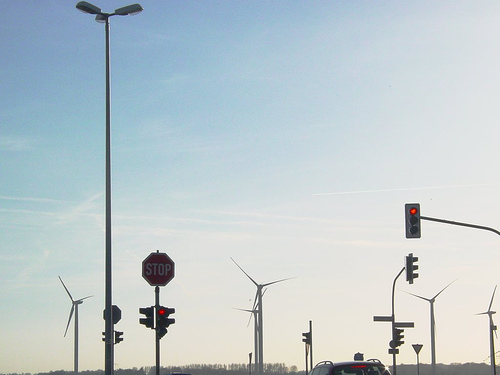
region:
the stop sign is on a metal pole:
[139, 249, 180, 287]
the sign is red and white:
[138, 250, 179, 285]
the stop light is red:
[401, 203, 427, 238]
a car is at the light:
[305, 356, 394, 374]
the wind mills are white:
[50, 273, 92, 374]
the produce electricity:
[47, 270, 96, 372]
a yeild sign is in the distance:
[410, 343, 427, 374]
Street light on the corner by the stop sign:
[69, 1, 155, 372]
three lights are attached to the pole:
[74, 0, 146, 27]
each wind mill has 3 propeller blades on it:
[54, 273, 92, 340]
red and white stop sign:
[137, 246, 177, 289]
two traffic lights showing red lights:
[137, 190, 424, 339]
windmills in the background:
[42, 256, 498, 363]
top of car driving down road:
[308, 355, 380, 374]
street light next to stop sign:
[78, 3, 141, 373]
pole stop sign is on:
[150, 288, 166, 374]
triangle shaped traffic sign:
[411, 340, 425, 354]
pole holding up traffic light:
[422, 208, 495, 247]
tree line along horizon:
[36, 360, 498, 374]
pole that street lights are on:
[102, 24, 117, 369]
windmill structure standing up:
[228, 262, 285, 374]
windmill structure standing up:
[53, 275, 92, 373]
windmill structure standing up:
[416, 285, 450, 370]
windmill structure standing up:
[473, 282, 495, 372]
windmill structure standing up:
[248, 300, 253, 367]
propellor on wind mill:
[54, 278, 94, 333]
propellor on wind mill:
[227, 260, 270, 306]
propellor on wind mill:
[413, 288, 465, 313]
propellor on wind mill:
[236, 308, 253, 330]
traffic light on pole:
[297, 330, 317, 347]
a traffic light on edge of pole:
[397, 192, 492, 242]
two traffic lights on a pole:
[136, 303, 178, 345]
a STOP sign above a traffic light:
[131, 245, 176, 370]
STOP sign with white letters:
[135, 245, 175, 290]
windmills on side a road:
[40, 251, 495, 371]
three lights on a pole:
[65, 0, 140, 366]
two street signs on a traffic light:
[365, 305, 416, 325]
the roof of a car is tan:
[295, 350, 400, 370]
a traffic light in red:
[150, 300, 175, 340]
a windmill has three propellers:
[53, 268, 101, 373]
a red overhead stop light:
[392, 188, 427, 245]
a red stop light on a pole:
[136, 293, 186, 341]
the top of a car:
[305, 351, 395, 373]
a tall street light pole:
[70, 0, 128, 374]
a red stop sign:
[136, 240, 186, 296]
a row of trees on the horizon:
[32, 354, 467, 374]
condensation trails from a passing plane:
[14, 192, 404, 258]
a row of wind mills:
[30, 273, 498, 373]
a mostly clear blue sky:
[8, 2, 493, 292]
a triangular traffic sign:
[405, 340, 429, 361]